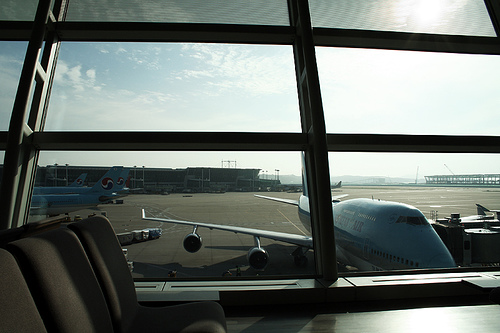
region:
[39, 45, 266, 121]
the sky is cloudy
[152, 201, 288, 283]
the engines are on the wing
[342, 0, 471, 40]
the sun is bright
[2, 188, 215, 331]
the shadow is on the chairs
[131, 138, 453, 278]
this is an airport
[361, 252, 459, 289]
the sun is on the window sill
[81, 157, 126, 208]
there is a red and blue circle on the tail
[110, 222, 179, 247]
the baggage cars are out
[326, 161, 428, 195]
it is foggy out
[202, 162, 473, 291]
the plane is parked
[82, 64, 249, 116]
the sky is bright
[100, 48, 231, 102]
the sky is bright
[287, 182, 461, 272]
a blue passenger airplane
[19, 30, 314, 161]
a portion of a black framed window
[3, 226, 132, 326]
a row of 3 interior seats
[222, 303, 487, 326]
a long black wooden table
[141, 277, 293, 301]
a gray window ledge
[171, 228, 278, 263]
two airplane engines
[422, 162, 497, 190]
a long airport overhang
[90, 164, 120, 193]
the Pepsi symbol on a plane's tail fin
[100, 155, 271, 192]
an airport terminal in the parking lot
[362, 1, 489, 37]
sunlight glowing through a plane window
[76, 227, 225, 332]
Brown seat in a waiting room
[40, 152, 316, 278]
Window overlooking an airport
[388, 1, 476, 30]
Sun shining in through a window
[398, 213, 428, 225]
Windshield on a plane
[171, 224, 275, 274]
Two engines on a plane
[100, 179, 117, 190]
Circle on a plane's tail fin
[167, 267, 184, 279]
Man working at an airport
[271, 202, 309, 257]
Line painted on an airport road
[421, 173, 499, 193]
Building behind an airport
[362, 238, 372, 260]
Door on the side of an airplane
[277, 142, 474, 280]
a plane on an airport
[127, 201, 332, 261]
left wing of plane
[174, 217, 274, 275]
two engines in a left wing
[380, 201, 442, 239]
narrow windows in a cockpit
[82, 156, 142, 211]
vertical stabilizer of a plane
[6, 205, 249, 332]
chair inside a building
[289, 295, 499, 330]
a table in front of chairs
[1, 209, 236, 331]
chairs are color brown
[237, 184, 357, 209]
two horizontal fins of a plane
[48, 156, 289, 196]
a building on side of landing strip